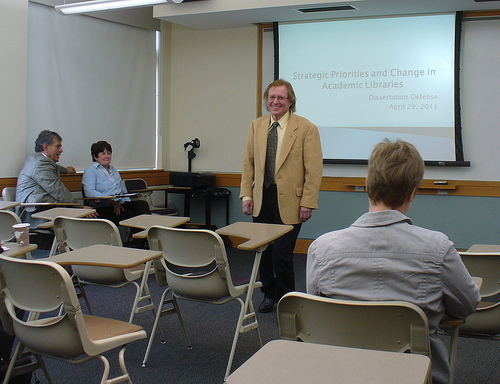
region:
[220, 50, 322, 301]
this is a man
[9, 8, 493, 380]
this is a class room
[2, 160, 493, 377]
desks in a class room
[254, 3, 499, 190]
this is a projection screen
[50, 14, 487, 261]
man standing in front of class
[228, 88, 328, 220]
man wearing a sports coat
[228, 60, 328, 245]
man is doing a lecture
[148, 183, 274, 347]
the chair is empty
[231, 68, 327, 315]
person standing in front of class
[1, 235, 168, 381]
tan desk and chair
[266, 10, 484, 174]
white and black screen in back of class room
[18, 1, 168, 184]
white shade drawn across window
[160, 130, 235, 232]
black projector in corner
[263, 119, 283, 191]
tie on man's shirt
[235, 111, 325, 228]
tan suit jacket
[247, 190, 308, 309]
pair of black pants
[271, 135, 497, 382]
person in grey jacket sitting at desk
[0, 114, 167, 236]
two people sitting at desk on side of room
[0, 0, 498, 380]
a classroom setting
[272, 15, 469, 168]
a power point presentation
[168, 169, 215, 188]
a black projector on a black table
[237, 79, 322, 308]
man standing at the front of the classroom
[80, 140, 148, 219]
woman sitting to the side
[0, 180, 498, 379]
group of chairs and desks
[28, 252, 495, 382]
gray carpeted floor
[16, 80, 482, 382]
people inside a classroom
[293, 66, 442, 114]
words on the screen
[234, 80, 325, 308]
a man standing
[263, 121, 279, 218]
a brown tie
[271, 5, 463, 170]
a screen with words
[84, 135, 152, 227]
a woman sitting at the desk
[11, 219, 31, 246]
a cup in holder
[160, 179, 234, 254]
a black stand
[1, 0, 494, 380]
a large classroom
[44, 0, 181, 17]
the hanging light in ceiling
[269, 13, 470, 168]
a retractable projector screen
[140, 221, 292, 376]
a school desk and chair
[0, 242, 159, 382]
a school desk and chair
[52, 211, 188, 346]
a school desk and chair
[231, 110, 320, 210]
man wearing a brown jacket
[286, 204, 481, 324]
man wearing a brown jacket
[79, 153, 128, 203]
woman wearing a white shirt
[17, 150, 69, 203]
man wearing a grey shirt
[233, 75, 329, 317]
man in khaki suit jacket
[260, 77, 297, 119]
smiling adult white male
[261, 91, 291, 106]
eyeglasses on man's face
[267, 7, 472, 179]
hanging projector screen with picture